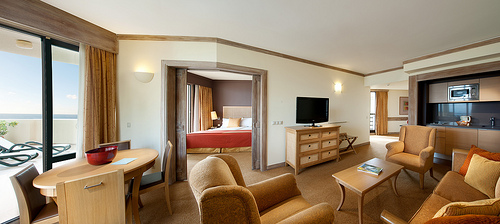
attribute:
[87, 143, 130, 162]
bowl — burgundy, large, red, sitting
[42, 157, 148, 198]
table — rounded, wooden, oval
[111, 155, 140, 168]
paper — white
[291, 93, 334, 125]
t.v. — black, small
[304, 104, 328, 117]
screen — flat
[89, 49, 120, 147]
curtain — open, brown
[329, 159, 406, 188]
table — center, in, coffee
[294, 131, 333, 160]
dresser — holding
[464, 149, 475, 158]
pillow — orange, square, brown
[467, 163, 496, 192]
pillow — beige, square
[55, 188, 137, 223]
chair — wooden, light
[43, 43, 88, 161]
door — glass, large, sliding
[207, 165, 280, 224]
chair — small, coach, brown, coushioned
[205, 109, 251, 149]
bed — large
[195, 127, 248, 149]
cover — orange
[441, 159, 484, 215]
couch — brown, light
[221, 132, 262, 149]
sheets — red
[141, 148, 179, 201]
chair — beige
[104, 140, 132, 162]
chair — beige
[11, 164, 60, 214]
chair — beige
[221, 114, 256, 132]
pillow — beige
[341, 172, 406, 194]
coffee-table — brown, small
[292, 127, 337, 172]
chest — brown, beige